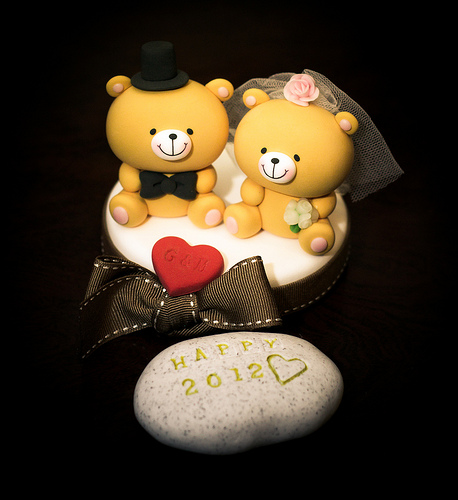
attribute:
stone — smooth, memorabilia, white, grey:
[135, 329, 348, 457]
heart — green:
[266, 354, 308, 384]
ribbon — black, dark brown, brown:
[78, 256, 282, 358]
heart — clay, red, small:
[153, 236, 224, 298]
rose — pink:
[281, 73, 319, 108]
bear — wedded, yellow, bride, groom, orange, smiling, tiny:
[224, 86, 360, 259]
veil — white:
[223, 69, 403, 203]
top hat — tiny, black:
[126, 41, 188, 92]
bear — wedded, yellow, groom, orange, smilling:
[100, 41, 234, 227]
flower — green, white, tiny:
[281, 199, 312, 233]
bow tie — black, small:
[137, 172, 199, 198]